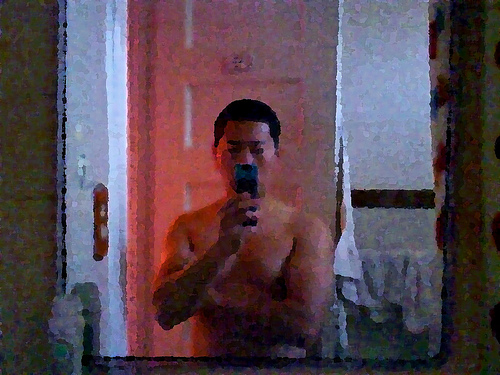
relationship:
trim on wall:
[351, 189, 431, 208] [340, 2, 445, 361]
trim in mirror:
[351, 189, 431, 208] [300, 47, 458, 358]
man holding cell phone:
[152, 99, 334, 366] [229, 160, 261, 224]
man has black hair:
[152, 99, 334, 366] [204, 97, 284, 154]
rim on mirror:
[440, 222, 456, 367] [59, 0, 453, 373]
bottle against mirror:
[42, 285, 95, 367] [59, 0, 453, 373]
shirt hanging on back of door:
[331, 131, 363, 280] [125, 0, 345, 363]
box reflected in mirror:
[94, 183, 110, 257] [59, 0, 453, 373]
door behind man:
[81, 27, 293, 252] [174, 106, 382, 327]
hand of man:
[199, 181, 276, 265] [146, 97, 336, 362]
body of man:
[191, 197, 306, 374] [147, 91, 357, 366]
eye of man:
[226, 144, 241, 156] [146, 97, 336, 362]